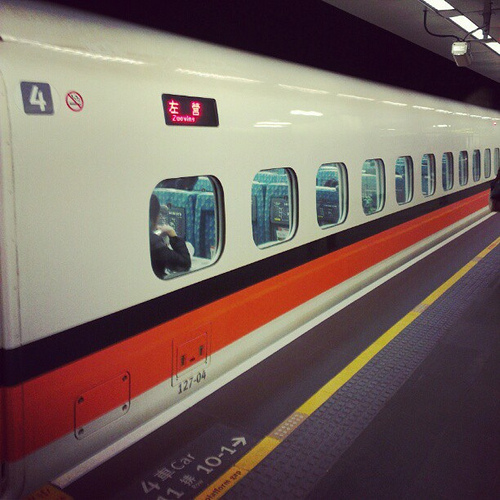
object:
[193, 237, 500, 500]
line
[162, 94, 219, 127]
red light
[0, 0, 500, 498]
train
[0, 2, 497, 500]
photo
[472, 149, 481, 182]
window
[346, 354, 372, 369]
mark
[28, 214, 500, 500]
sidewalk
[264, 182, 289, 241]
sits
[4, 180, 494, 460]
line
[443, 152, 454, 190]
window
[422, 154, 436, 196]
window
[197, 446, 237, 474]
numbers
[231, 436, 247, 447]
arrow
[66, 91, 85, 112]
sign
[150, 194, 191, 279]
person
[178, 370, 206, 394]
number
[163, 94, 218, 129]
signage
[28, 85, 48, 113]
number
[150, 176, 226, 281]
glass window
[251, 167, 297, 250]
glass window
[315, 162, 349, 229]
glass window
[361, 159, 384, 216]
glass window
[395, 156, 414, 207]
glass window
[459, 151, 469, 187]
window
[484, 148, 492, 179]
window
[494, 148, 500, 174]
window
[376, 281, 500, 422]
black line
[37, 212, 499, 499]
platform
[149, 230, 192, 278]
top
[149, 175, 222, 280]
glass panes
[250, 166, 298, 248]
glass panes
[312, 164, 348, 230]
glass panes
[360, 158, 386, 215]
glass panes